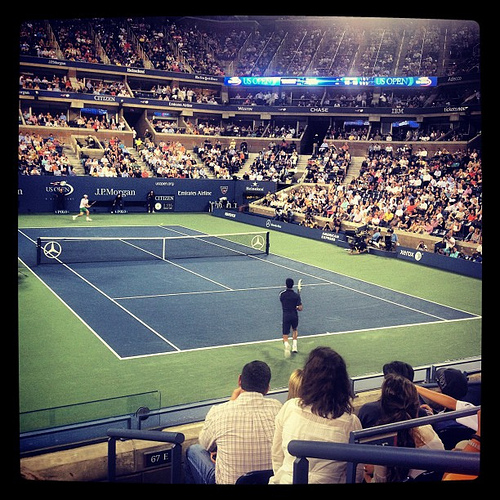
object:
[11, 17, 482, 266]
spectator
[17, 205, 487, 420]
tennis match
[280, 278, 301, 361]
man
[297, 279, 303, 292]
bat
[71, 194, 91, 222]
player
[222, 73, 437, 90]
scoreboard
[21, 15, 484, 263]
stands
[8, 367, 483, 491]
stands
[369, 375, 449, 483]
spectators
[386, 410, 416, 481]
ponytail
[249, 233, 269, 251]
logo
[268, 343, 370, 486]
lady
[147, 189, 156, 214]
boy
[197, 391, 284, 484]
plaid shirt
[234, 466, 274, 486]
blue jeans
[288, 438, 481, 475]
top rail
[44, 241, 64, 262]
marker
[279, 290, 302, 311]
shirt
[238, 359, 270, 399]
head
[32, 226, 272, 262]
net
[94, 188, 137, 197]
jp morgan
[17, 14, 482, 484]
arena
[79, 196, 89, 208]
shirt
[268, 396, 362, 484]
shirt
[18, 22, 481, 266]
seating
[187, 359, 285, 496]
man